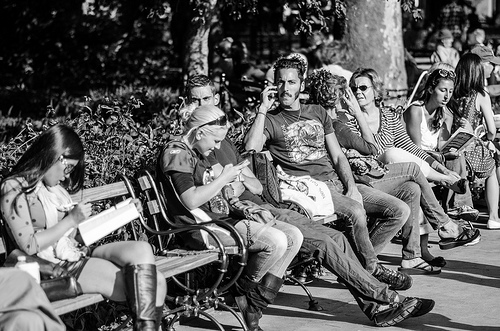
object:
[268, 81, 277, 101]
phone